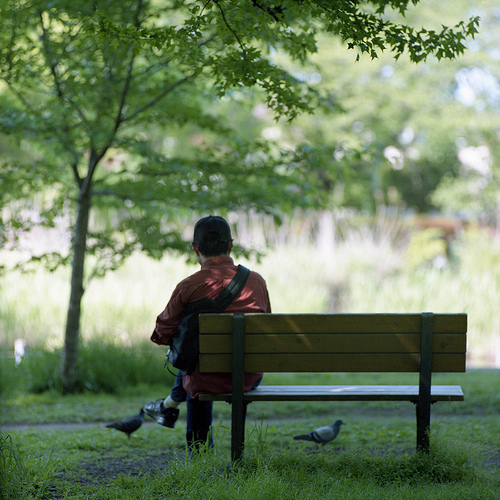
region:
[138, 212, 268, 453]
the person sitting on the bench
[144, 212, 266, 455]
the only person on the bench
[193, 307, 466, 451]
the wooden bench in the park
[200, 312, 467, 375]
the three pieces of wood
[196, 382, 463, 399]
the seat of the bench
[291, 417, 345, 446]
the bird under the bench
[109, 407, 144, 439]
the bird by the man's foot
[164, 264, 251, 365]
the bag on the man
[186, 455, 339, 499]
the grass on the ground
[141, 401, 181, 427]
the man's black shoe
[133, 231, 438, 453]
the bench is wooden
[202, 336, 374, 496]
the bench is wooden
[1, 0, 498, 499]
man on bench in park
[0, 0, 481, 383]
healthy tree in park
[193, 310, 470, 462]
wooden bench in park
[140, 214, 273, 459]
man wearing dark cap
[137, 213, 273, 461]
man wearing dark backpack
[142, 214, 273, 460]
man wearing dark shoe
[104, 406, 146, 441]
pidgeon walking on left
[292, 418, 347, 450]
pidgeon walking on right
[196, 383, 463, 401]
seat on wooden bench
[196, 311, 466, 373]
back of wooden bench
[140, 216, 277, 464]
a man sitting on a bench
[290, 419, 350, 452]
a small bird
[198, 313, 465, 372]
wooden panels on the back of a bench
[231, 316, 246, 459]
metal support for a bench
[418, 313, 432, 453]
metal support for a bench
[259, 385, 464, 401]
the wooden seat of a bench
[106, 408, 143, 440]
a small black bird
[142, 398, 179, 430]
a man's shoe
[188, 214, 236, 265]
the back of a man's head who is wearing a hat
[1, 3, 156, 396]
a tree in the distance